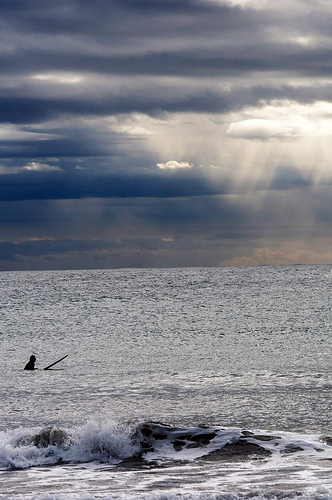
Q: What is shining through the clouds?
A: Sun.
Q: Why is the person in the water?
A: Surfing.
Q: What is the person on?
A: Surfboard.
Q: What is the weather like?
A: Cloudy.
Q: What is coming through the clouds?
A: The sun.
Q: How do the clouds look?
A: Dark.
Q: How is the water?
A: Blue.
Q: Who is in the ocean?
A: A man.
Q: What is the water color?
A: Blue.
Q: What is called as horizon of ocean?
A: Sky and ocean meet.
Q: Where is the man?
A: In water.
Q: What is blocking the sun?
A: Clouds.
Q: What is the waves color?
A: White.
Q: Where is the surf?
A: In wave.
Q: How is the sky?
A: Cloudy.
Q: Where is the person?
A: In the water.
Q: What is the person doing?
A: Sitting in the water.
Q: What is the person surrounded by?
A: Water.